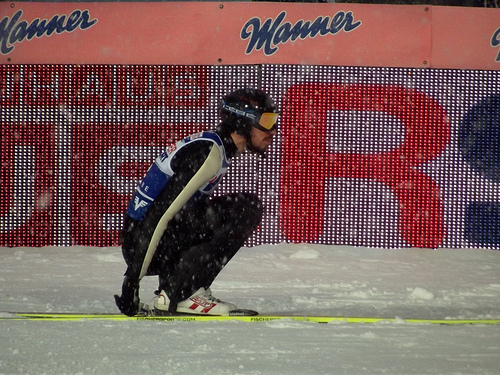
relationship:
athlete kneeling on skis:
[112, 88, 278, 316] [2, 306, 500, 329]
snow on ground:
[7, 248, 500, 362] [7, 247, 495, 366]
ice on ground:
[9, 248, 499, 365] [7, 247, 495, 366]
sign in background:
[3, 67, 499, 247] [5, 6, 500, 248]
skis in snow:
[2, 306, 500, 329] [7, 248, 500, 362]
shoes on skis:
[154, 286, 232, 316] [2, 306, 500, 329]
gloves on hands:
[113, 274, 145, 315] [113, 272, 141, 314]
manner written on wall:
[237, 10, 364, 61] [7, 8, 499, 245]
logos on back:
[3, 1, 500, 52] [2, 4, 498, 244]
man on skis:
[101, 86, 279, 314] [2, 306, 500, 329]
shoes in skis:
[149, 285, 233, 313] [2, 306, 500, 329]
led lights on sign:
[4, 70, 496, 242] [3, 5, 499, 247]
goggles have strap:
[216, 100, 278, 129] [222, 100, 256, 117]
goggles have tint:
[216, 100, 278, 129] [263, 113, 280, 129]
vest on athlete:
[122, 127, 229, 218] [112, 88, 278, 316]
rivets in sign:
[5, 0, 437, 66] [3, 5, 499, 247]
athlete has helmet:
[112, 88, 278, 316] [221, 88, 278, 136]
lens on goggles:
[260, 110, 279, 131] [221, 104, 279, 132]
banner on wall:
[2, 6, 499, 67] [7, 8, 499, 245]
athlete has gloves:
[112, 88, 278, 316] [113, 274, 145, 315]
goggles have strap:
[221, 104, 279, 132] [222, 100, 256, 117]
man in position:
[101, 86, 279, 314] [103, 85, 293, 311]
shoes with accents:
[154, 286, 232, 316] [189, 293, 218, 315]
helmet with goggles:
[213, 81, 279, 128] [216, 100, 278, 129]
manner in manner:
[237, 10, 363, 57] [237, 10, 363, 57]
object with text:
[11, 305, 499, 331] [16, 316, 442, 322]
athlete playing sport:
[115, 86, 283, 310] [3, 5, 496, 365]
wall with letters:
[7, 8, 499, 245] [5, 70, 497, 238]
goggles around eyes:
[216, 100, 278, 129] [262, 119, 283, 134]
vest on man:
[122, 127, 229, 218] [101, 86, 279, 314]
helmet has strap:
[213, 81, 279, 128] [222, 100, 256, 117]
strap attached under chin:
[222, 100, 256, 117] [247, 143, 266, 152]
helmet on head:
[213, 81, 279, 128] [221, 84, 286, 153]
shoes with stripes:
[154, 286, 232, 316] [188, 295, 221, 314]